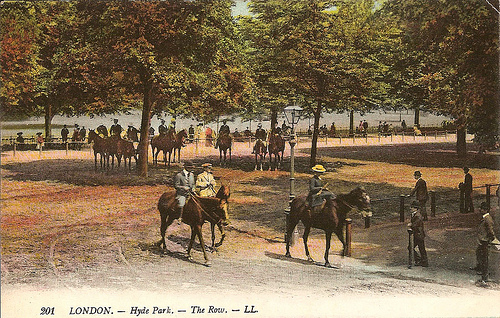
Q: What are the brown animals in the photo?
A: Horses.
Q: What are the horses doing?
A: Walking slowly with riders.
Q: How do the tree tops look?
A: Green and brown.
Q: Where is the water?
A: Just beyond where people are sitting on benches.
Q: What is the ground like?
A: Brown with soft dirt.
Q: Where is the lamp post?
A: Just behind the woman in the yellow hat.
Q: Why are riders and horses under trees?
A: It is shady.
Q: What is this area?
A: A park.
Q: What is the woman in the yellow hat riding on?
A: A horse.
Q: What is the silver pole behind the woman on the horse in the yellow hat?
A: A lamp post.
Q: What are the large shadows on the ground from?
A: Trees.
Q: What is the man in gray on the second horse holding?
A: The reins.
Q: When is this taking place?
A: Daytime.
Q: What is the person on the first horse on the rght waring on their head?
A: Hat.